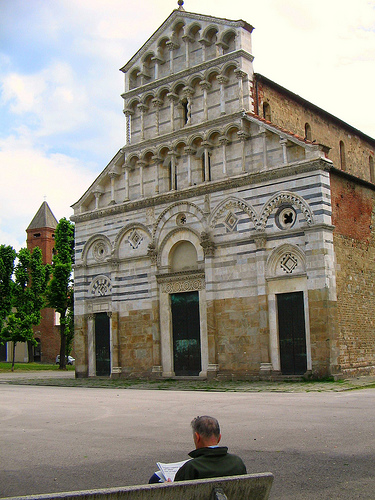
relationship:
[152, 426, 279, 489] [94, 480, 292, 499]
man on bench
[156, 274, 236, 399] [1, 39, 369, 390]
door on building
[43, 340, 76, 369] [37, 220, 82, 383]
vehicle behind tree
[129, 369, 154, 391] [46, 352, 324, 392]
weed on walkway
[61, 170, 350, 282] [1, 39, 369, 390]
window on building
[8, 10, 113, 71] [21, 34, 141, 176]
cloud in sky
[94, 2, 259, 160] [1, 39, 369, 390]
design on top of building